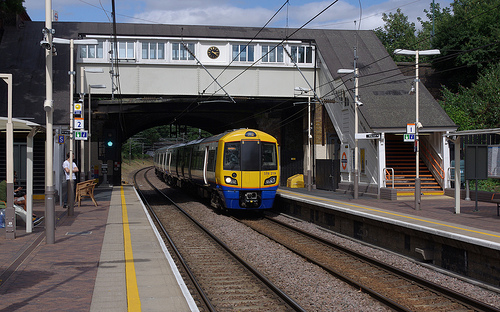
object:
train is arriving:
[1, 1, 499, 312]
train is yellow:
[154, 125, 279, 211]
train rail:
[241, 216, 496, 310]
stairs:
[385, 173, 434, 177]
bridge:
[54, 19, 317, 100]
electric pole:
[413, 50, 424, 216]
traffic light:
[107, 140, 114, 147]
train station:
[0, 0, 499, 311]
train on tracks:
[155, 126, 482, 310]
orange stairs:
[386, 184, 444, 190]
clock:
[207, 46, 220, 59]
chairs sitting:
[75, 178, 96, 201]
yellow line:
[120, 184, 140, 311]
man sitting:
[4, 173, 46, 229]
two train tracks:
[134, 165, 497, 310]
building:
[8, 18, 457, 197]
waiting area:
[2, 117, 106, 249]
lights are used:
[393, 47, 441, 210]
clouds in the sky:
[130, 0, 284, 27]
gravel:
[314, 280, 330, 293]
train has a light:
[224, 174, 235, 185]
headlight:
[244, 130, 258, 139]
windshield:
[223, 141, 279, 170]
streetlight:
[396, 47, 441, 57]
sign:
[74, 116, 85, 128]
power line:
[173, 3, 334, 125]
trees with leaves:
[380, 4, 418, 63]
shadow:
[2, 256, 154, 311]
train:
[150, 127, 282, 218]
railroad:
[131, 166, 500, 312]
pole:
[413, 54, 422, 212]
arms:
[62, 162, 70, 173]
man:
[59, 150, 80, 209]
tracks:
[298, 229, 495, 309]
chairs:
[76, 183, 97, 207]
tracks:
[150, 186, 304, 312]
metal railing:
[259, 212, 466, 298]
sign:
[74, 130, 89, 139]